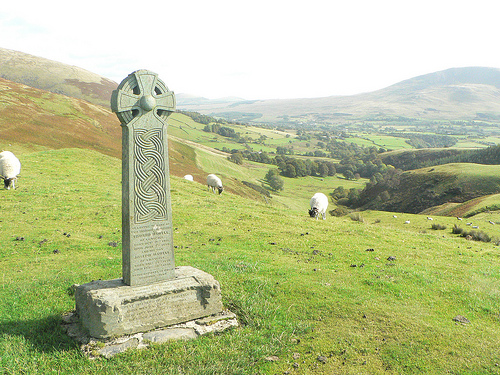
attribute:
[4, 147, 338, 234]
sheep — short, white, standing, black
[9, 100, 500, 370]
grass — short, green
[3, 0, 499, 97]
sky — open, big, bright, white, clear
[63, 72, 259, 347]
tombstone — gray, grey, long, tall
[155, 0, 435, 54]
sky — clear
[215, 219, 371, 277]
epitaph — gray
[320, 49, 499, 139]
hills — tall